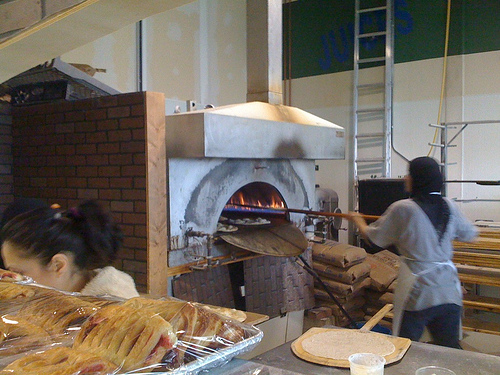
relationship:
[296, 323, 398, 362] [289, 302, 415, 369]
dough on tray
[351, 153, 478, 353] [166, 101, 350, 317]
woman by oven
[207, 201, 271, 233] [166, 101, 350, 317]
pizza in oven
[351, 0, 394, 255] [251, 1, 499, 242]
ladder against wall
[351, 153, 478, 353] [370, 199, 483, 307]
woman in shirt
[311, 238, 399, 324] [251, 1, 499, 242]
flower in background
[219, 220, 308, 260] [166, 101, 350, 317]
door to oven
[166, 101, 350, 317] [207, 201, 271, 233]
oven for pizza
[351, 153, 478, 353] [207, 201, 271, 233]
woman placing pizza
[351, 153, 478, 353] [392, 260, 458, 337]
woman wearing apron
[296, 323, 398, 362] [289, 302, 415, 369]
dough on board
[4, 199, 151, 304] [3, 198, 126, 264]
woman with pony tail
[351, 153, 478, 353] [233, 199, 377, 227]
woman holding spatula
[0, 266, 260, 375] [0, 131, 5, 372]
danish on left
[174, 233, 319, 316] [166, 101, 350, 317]
brick under oven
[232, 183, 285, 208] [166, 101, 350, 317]
fire in oven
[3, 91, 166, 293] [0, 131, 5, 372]
brick on left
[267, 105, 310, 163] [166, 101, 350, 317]
mark on oven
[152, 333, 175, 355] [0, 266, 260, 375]
berry filled strudels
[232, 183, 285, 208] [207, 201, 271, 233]
fire baked pizza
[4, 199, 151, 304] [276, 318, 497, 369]
countertop by counter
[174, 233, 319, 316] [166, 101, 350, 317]
brick surrounds oven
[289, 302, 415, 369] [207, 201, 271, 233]
board for pizza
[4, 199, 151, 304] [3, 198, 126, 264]
woman has hair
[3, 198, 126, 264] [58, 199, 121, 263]
hair in ponytail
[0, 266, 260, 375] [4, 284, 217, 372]
pastry covered with wrap